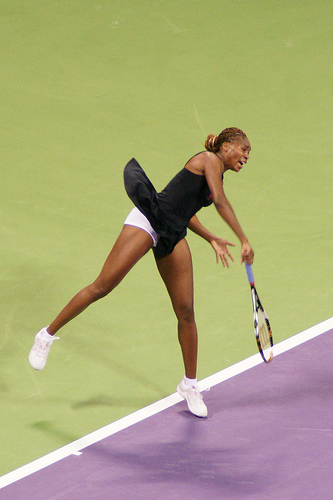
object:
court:
[0, 315, 333, 498]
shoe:
[27, 327, 55, 370]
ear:
[222, 142, 229, 149]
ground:
[0, 0, 333, 500]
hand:
[211, 235, 236, 268]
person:
[28, 128, 251, 418]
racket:
[240, 249, 274, 363]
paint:
[281, 316, 333, 352]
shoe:
[177, 379, 208, 417]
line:
[135, 237, 306, 486]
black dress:
[123, 150, 224, 260]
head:
[218, 126, 251, 173]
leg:
[46, 207, 153, 336]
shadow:
[30, 395, 273, 498]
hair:
[205, 127, 247, 153]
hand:
[240, 235, 254, 265]